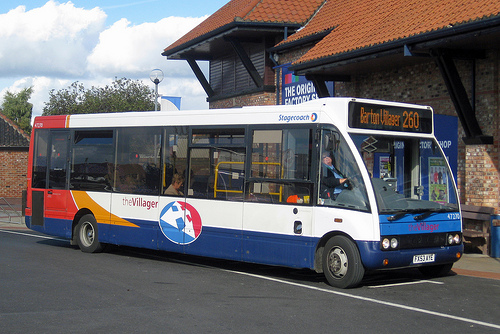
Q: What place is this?
A: It is a store.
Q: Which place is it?
A: It is a store.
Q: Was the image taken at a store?
A: Yes, it was taken in a store.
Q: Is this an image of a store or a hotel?
A: It is showing a store.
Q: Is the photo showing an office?
A: No, the picture is showing a store.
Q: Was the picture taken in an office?
A: No, the picture was taken in a store.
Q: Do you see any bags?
A: No, there are no bags.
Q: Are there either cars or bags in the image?
A: No, there are no bags or cars.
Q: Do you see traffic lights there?
A: No, there are no traffic lights.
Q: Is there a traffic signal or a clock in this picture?
A: No, there are no traffic lights or clocks.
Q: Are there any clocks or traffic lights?
A: No, there are no traffic lights or clocks.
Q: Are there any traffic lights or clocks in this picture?
A: No, there are no traffic lights or clocks.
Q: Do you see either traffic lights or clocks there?
A: No, there are no traffic lights or clocks.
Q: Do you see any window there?
A: Yes, there is a window.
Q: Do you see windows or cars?
A: Yes, there is a window.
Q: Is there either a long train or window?
A: Yes, there is a long window.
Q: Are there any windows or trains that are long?
A: Yes, the window is long.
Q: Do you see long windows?
A: Yes, there is a long window.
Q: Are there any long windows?
A: Yes, there is a long window.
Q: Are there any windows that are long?
A: Yes, there is a window that is long.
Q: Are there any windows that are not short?
A: Yes, there is a long window.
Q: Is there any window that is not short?
A: Yes, there is a long window.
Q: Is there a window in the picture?
A: Yes, there are windows.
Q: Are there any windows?
A: Yes, there are windows.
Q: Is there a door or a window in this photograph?
A: Yes, there are windows.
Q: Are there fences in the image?
A: No, there are no fences.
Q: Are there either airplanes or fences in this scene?
A: No, there are no fences or airplanes.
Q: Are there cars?
A: No, there are no cars.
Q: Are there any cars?
A: No, there are no cars.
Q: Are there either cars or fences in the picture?
A: No, there are no cars or fences.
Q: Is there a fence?
A: No, there are no fences.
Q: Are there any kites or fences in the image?
A: No, there are no fences or kites.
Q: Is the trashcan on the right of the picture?
A: Yes, the trashcan is on the right of the image.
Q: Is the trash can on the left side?
A: No, the trash can is on the right of the image.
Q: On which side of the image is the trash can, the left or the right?
A: The trash can is on the right of the image.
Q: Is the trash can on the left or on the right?
A: The trash can is on the right of the image.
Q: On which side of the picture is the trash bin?
A: The trash bin is on the right of the image.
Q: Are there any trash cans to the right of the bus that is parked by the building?
A: Yes, there is a trash can to the right of the bus.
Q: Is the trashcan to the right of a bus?
A: Yes, the trashcan is to the right of a bus.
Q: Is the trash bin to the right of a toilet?
A: No, the trash bin is to the right of a bus.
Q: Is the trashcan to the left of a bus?
A: No, the trashcan is to the right of a bus.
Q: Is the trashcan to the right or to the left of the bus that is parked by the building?
A: The trashcan is to the right of the bus.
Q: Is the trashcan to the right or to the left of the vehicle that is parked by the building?
A: The trashcan is to the right of the bus.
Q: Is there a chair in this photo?
A: No, there are no chairs.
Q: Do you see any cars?
A: No, there are no cars.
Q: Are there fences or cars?
A: No, there are no cars or fences.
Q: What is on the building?
A: The sign is on the building.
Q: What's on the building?
A: The sign is on the building.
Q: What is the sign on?
A: The sign is on the building.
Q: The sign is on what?
A: The sign is on the building.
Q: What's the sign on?
A: The sign is on the building.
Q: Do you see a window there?
A: Yes, there is a window.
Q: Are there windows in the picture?
A: Yes, there is a window.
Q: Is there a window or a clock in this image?
A: Yes, there is a window.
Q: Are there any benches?
A: Yes, there is a bench.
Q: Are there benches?
A: Yes, there is a bench.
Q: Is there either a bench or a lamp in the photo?
A: Yes, there is a bench.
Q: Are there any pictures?
A: No, there are no pictures.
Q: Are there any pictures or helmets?
A: No, there are no pictures or helmets.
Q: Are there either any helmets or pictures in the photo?
A: No, there are no pictures or helmets.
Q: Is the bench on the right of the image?
A: Yes, the bench is on the right of the image.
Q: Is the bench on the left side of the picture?
A: No, the bench is on the right of the image.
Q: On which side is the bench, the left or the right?
A: The bench is on the right of the image.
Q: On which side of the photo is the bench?
A: The bench is on the right of the image.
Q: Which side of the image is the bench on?
A: The bench is on the right of the image.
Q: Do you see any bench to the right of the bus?
A: Yes, there is a bench to the right of the bus.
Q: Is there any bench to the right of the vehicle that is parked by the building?
A: Yes, there is a bench to the right of the bus.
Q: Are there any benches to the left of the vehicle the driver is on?
A: No, the bench is to the right of the bus.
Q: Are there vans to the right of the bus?
A: No, there is a bench to the right of the bus.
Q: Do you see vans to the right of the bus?
A: No, there is a bench to the right of the bus.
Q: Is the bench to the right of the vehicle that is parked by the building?
A: Yes, the bench is to the right of the bus.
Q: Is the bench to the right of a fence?
A: No, the bench is to the right of the bus.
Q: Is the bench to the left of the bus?
A: No, the bench is to the right of the bus.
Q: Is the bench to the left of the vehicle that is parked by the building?
A: No, the bench is to the right of the bus.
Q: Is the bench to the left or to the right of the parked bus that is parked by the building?
A: The bench is to the right of the bus.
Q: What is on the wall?
A: The bench is on the wall.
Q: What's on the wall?
A: The bench is on the wall.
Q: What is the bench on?
A: The bench is on the wall.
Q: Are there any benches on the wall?
A: Yes, there is a bench on the wall.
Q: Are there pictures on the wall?
A: No, there is a bench on the wall.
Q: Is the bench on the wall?
A: Yes, the bench is on the wall.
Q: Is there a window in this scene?
A: Yes, there is a window.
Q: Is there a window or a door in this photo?
A: Yes, there is a window.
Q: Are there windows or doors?
A: Yes, there is a window.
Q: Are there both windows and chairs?
A: No, there is a window but no chairs.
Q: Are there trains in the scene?
A: No, there are no trains.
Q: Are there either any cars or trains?
A: No, there are no trains or cars.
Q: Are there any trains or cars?
A: No, there are no trains or cars.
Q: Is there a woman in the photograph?
A: Yes, there is a woman.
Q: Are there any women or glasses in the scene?
A: Yes, there is a woman.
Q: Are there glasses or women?
A: Yes, there is a woman.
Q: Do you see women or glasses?
A: Yes, there is a woman.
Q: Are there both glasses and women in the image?
A: No, there is a woman but no glasses.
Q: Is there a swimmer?
A: No, there are no swimmers.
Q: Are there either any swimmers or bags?
A: No, there are no swimmers or bags.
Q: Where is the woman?
A: The woman is on the bus.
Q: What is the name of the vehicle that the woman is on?
A: The vehicle is a bus.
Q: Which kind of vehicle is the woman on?
A: The woman is on the bus.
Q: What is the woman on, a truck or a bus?
A: The woman is on a bus.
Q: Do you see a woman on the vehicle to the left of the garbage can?
A: Yes, there is a woman on the bus.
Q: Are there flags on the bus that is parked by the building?
A: No, there is a woman on the bus.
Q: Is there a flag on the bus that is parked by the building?
A: No, there is a woman on the bus.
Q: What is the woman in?
A: The woman is in the window.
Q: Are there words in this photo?
A: Yes, there are words.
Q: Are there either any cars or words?
A: Yes, there are words.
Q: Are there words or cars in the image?
A: Yes, there are words.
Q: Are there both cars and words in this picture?
A: No, there are words but no cars.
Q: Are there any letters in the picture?
A: Yes, there are letters.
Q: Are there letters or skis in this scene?
A: Yes, there are letters.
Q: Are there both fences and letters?
A: No, there are letters but no fences.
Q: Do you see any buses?
A: Yes, there is a bus.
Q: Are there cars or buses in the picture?
A: Yes, there is a bus.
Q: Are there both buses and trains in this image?
A: No, there is a bus but no trains.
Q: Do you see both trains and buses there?
A: No, there is a bus but no trains.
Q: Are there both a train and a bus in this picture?
A: No, there is a bus but no trains.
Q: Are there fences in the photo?
A: No, there are no fences.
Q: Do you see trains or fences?
A: No, there are no fences or trains.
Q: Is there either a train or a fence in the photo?
A: No, there are no fences or trains.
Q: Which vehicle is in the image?
A: The vehicle is a bus.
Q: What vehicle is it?
A: The vehicle is a bus.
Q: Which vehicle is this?
A: This is a bus.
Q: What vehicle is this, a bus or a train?
A: This is a bus.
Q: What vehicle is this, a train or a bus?
A: This is a bus.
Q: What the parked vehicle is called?
A: The vehicle is a bus.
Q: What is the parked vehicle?
A: The vehicle is a bus.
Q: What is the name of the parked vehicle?
A: The vehicle is a bus.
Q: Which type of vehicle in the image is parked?
A: The vehicle is a bus.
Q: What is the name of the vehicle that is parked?
A: The vehicle is a bus.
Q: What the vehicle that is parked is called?
A: The vehicle is a bus.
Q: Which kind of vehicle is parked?
A: The vehicle is a bus.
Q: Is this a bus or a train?
A: This is a bus.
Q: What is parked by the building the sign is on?
A: The bus is parked by the building.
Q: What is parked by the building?
A: The bus is parked by the building.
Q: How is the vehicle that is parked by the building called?
A: The vehicle is a bus.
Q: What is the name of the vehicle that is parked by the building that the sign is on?
A: The vehicle is a bus.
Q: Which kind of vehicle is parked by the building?
A: The vehicle is a bus.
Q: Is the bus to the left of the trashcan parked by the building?
A: Yes, the bus is parked by the building.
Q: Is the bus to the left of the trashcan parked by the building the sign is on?
A: Yes, the bus is parked by the building.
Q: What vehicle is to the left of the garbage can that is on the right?
A: The vehicle is a bus.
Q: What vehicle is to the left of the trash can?
A: The vehicle is a bus.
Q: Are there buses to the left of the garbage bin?
A: Yes, there is a bus to the left of the garbage bin.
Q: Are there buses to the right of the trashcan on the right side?
A: No, the bus is to the left of the trash can.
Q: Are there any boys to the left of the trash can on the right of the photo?
A: No, there is a bus to the left of the garbage bin.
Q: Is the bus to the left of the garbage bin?
A: Yes, the bus is to the left of the garbage bin.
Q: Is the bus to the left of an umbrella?
A: No, the bus is to the left of the garbage bin.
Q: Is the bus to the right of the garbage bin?
A: No, the bus is to the left of the garbage bin.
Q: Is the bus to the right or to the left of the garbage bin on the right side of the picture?
A: The bus is to the left of the trash can.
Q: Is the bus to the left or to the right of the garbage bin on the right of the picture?
A: The bus is to the left of the trash can.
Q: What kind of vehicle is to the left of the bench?
A: The vehicle is a bus.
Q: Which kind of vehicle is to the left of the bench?
A: The vehicle is a bus.